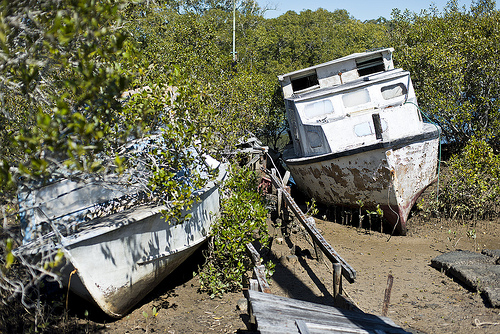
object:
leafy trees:
[109, 19, 200, 74]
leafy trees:
[418, 31, 492, 99]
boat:
[0, 107, 233, 317]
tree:
[0, 0, 220, 269]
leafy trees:
[240, 19, 336, 53]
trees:
[260, 7, 391, 67]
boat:
[277, 47, 442, 242]